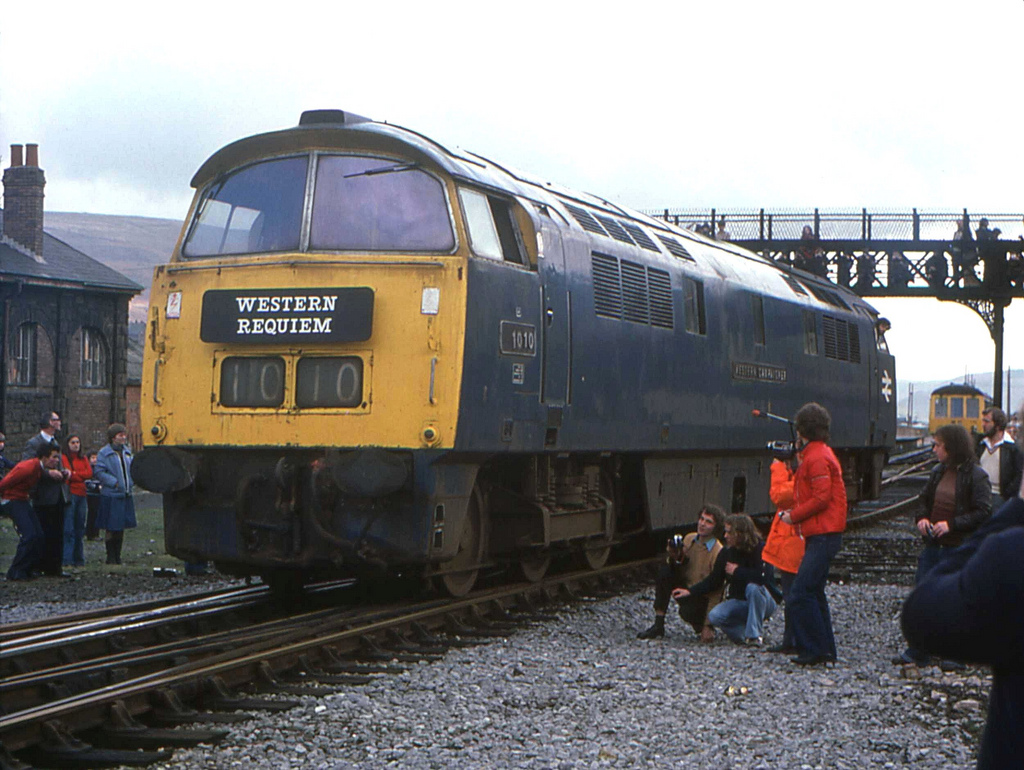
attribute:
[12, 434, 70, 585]
man — bending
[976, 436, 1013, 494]
shirt — white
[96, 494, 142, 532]
skirt — blue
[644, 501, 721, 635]
man — crouching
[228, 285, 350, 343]
letters — white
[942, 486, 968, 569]
shirt — brown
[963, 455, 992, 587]
jacket — black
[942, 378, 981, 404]
train — yellow and black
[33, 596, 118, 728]
tracks — brown and metal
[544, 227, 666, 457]
engine — black, yellow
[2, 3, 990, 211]
sky — blue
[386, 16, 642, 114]
clouds — white